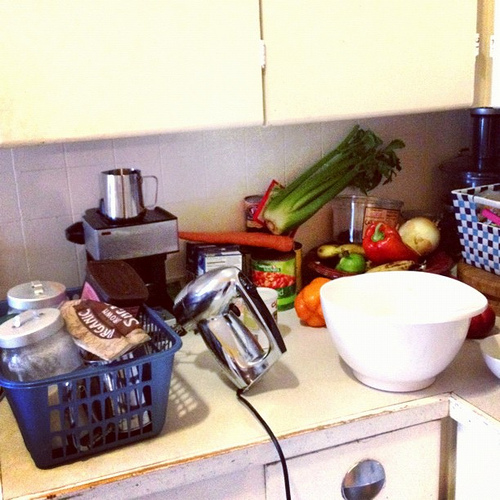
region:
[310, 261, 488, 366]
white bowl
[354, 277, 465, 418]
white bowl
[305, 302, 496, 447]
white bowl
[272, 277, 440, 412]
white bowl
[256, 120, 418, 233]
the vegetable is green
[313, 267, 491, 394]
a big white bowl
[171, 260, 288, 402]
this is a kettle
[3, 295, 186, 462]
this is a basket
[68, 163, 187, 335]
this is a coffee maker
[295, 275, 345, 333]
this is yellow pepper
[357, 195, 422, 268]
this is red pepper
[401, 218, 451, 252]
this is a white onion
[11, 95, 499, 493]
this a kitchen counter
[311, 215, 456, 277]
these are vegetables in a tray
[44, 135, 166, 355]
silver coffee maker on counter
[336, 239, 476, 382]
white bowl on the counter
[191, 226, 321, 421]
silver mixer on counter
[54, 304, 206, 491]
blue basket on the counter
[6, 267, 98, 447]
jars inside basket on counter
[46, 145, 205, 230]
silver coffee mug on top of coffee maker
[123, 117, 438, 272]
celery in background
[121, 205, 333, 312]
carrots on top of boxes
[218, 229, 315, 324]
diced tomatoes in a can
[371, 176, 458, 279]
red pepper and onion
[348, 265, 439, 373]
Large white bowl on counter top.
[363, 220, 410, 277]
Red pepper sitting in bowl.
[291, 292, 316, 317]
Orange pepper on counter.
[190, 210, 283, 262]
Large orange carrot on counter.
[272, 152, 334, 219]
Green celery on counter.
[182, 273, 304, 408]
Silver hand mixer on counter.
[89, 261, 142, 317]
Brown lid on container.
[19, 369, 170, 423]
Blue basket sitting on counter.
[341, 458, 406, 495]
Silver handle on drawer.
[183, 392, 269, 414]
Counter top is white.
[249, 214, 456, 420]
the bowl is white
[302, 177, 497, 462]
the bowl is white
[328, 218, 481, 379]
the bowl is white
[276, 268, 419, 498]
the bowl is white